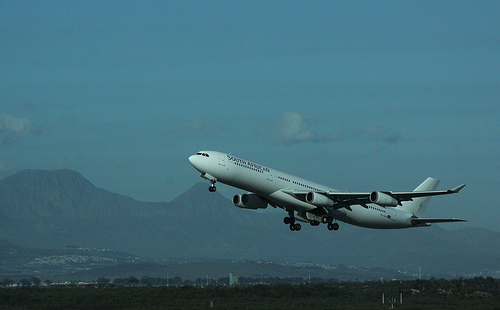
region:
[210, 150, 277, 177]
"South American" on the plane.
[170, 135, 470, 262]
The plane is white.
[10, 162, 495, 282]
Mountains in the background.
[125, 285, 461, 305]
The trees are green.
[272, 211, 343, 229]
The wheels are down.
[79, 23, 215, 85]
The sky is blue.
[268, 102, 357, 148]
Cloud in the sky.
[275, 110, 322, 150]
The cloud is white and grey.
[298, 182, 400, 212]
Engines on the wing.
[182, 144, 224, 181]
Cockpit of the plane.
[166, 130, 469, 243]
A airplane flying in the air.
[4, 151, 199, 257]
A mountain in the background.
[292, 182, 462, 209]
A wing with two jets.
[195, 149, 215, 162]
Cockpit airplane windows.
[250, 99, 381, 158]
A white cloud in the sky.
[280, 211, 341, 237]
Landing gear on a airplane.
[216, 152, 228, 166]
A door on side of plane.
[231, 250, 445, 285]
A distant city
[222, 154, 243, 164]
The word South on side of plane.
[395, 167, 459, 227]
A tail on a airplane.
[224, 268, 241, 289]
tall building on ground below plane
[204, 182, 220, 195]
front landing gear of plane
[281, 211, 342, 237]
rear landing tires on plane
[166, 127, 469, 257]
plane taking off from airport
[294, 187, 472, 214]
engines of plane on wing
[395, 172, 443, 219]
tail of plane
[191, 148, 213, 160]
windows to the cock pit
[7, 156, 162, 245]
mountains in the background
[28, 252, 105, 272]
buildings in the distance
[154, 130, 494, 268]
plane in front of mountains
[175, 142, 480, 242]
Plane in the sky.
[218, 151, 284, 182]
"South American" on the plane.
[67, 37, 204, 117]
The sky is blue.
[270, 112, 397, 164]
Cloud in the sky.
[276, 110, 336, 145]
Cloud is grey and white.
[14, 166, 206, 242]
Mountain in the background.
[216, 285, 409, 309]
The trees are green.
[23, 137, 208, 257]
Fog in the sky.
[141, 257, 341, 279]
The ground is brown.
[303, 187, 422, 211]
Engine on the plane.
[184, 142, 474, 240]
a plane in the sky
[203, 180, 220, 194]
a black plane wheel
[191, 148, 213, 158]
the windshield of a plane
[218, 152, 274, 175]
writing on the plane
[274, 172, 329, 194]
a row of windows on the plane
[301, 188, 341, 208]
an engine on the plane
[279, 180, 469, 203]
a wing on the plane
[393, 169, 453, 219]
the tail on the plane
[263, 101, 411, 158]
a cloud in the sky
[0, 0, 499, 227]
a hazy blue sky